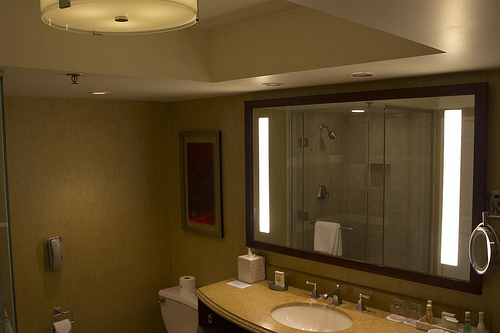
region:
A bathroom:
[2, 24, 497, 326]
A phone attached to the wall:
[40, 232, 65, 274]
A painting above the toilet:
[173, 125, 225, 248]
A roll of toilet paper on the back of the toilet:
[175, 268, 200, 300]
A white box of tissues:
[235, 245, 266, 280]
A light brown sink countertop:
[198, 262, 458, 330]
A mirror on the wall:
[245, 86, 486, 286]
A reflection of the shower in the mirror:
[240, 86, 470, 287]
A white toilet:
[126, 278, 201, 329]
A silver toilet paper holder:
[47, 304, 74, 327]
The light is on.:
[38, 1, 203, 37]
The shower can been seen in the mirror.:
[286, 106, 440, 278]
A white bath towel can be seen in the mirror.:
[308, 217, 358, 254]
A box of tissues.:
[237, 248, 265, 280]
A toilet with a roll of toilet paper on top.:
[153, 268, 197, 331]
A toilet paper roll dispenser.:
[50, 305, 78, 332]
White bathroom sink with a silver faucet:
[270, 278, 367, 332]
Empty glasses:
[386, 297, 423, 321]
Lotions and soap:
[423, 296, 486, 331]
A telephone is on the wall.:
[45, 231, 67, 271]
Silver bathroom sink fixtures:
[297, 271, 382, 313]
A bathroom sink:
[264, 268, 393, 332]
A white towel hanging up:
[305, 215, 354, 263]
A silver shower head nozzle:
[315, 123, 338, 144]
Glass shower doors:
[285, 103, 436, 278]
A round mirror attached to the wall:
[460, 195, 498, 274]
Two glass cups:
[387, 291, 424, 330]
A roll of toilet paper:
[47, 303, 73, 332]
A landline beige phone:
[47, 233, 70, 275]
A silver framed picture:
[171, 120, 231, 252]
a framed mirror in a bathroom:
[243, 82, 489, 293]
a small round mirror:
[468, 215, 498, 273]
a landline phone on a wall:
[43, 235, 64, 273]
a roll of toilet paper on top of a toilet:
[177, 275, 197, 295]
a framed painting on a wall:
[178, 128, 223, 239]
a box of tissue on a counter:
[237, 245, 264, 285]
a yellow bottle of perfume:
[424, 299, 434, 324]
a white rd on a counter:
[228, 277, 252, 288]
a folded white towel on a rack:
[312, 218, 340, 255]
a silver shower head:
[319, 121, 336, 143]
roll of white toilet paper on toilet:
[156, 273, 196, 329]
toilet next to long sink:
[155, 275, 425, 327]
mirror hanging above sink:
[190, 80, 495, 330]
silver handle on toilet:
[155, 282, 195, 327]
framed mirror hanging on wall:
[165, 66, 495, 316]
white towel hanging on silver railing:
[305, 215, 352, 251]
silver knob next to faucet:
[302, 276, 342, 306]